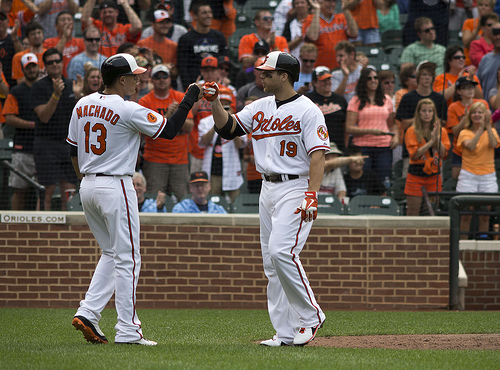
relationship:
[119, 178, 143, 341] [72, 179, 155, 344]
stripe on pants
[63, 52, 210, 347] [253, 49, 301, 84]
baseball player wearing cap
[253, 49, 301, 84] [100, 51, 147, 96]
cap on head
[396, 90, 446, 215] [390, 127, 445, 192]
woman wearing orange shirt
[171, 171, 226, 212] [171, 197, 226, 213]
man wearing shirt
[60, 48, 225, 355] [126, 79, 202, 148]
baseball player wearing black sleeves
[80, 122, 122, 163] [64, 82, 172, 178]
number on jersey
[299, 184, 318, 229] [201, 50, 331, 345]
glove on baseball player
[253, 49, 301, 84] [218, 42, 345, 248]
cap on baseball player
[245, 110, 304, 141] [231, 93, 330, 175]
orioles print on baseball jersey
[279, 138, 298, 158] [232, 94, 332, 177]
number 19 on jersey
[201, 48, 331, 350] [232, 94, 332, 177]
baseball player has jersey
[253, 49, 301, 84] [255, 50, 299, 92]
cap on head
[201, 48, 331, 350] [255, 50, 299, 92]
baseball player has head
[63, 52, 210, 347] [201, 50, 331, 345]
baseball player bumping fists with baseball player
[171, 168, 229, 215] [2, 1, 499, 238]
man in audience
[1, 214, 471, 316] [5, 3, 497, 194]
brick wall separating audience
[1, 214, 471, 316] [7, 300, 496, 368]
brick wall separating field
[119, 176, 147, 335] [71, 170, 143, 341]
stripe on pants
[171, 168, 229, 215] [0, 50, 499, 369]
man watching baseball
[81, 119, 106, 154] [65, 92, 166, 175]
number 13 on shirt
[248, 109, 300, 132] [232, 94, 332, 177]
name on a jersey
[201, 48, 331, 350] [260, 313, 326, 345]
baseball player wearing cleats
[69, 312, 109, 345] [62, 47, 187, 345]
shoe on player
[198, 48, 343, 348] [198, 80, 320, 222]
baseball player wearing gloves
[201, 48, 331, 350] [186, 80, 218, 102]
baseball player touching hands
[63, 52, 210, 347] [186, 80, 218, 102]
baseball player touching hands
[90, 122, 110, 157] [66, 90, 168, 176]
number on jersey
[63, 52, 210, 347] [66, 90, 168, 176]
baseball player has jersey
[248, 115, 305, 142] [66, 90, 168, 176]
logo on jersey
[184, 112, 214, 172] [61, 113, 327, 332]
baseball players knuckle touching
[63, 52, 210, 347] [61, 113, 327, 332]
baseball player players knuckle touching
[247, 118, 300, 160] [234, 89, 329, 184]
orioles written on jersey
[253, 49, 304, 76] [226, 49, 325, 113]
cap on mans head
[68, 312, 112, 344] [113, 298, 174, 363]
shoe on players foot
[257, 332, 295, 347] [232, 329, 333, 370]
shoe on players foot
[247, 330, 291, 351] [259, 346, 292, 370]
shoe on players foot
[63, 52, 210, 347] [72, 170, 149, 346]
baseball player wearing pants